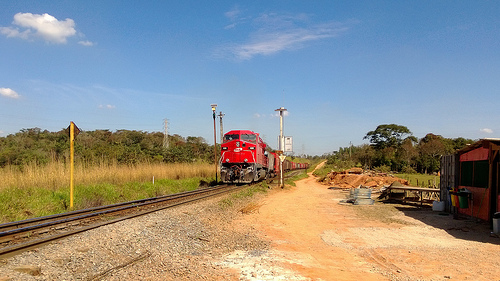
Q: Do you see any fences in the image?
A: No, there are no fences.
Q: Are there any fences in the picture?
A: No, there are no fences.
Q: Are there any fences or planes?
A: No, there are no fences or planes.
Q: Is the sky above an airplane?
A: No, the sky is above a train.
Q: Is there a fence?
A: No, there are no fences.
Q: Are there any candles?
A: No, there are no candles.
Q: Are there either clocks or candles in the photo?
A: No, there are no candles or clocks.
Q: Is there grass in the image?
A: Yes, there is grass.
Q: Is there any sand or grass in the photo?
A: Yes, there is grass.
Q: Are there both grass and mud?
A: No, there is grass but no mud.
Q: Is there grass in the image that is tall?
A: Yes, there is tall grass.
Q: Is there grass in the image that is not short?
A: Yes, there is tall grass.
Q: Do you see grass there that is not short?
A: Yes, there is tall grass.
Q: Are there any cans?
A: No, there are no cans.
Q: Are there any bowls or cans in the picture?
A: No, there are no cans or bowls.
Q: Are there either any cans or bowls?
A: No, there are no cans or bowls.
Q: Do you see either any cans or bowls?
A: No, there are no cans or bowls.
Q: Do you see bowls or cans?
A: No, there are no cans or bowls.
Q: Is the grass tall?
A: Yes, the grass is tall.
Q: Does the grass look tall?
A: Yes, the grass is tall.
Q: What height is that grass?
A: The grass is tall.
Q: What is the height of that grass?
A: The grass is tall.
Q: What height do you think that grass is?
A: The grass is tall.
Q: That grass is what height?
A: The grass is tall.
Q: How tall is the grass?
A: The grass is tall.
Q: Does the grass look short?
A: No, the grass is tall.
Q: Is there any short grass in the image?
A: No, there is grass but it is tall.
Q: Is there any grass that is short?
A: No, there is grass but it is tall.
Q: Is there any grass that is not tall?
A: No, there is grass but it is tall.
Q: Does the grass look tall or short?
A: The grass is tall.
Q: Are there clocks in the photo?
A: No, there are no clocks.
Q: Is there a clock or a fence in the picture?
A: No, there are no clocks or fences.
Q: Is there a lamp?
A: No, there are no lamps.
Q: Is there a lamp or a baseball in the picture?
A: No, there are no lamps or baseballs.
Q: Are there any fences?
A: No, there are no fences.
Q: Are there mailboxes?
A: No, there are no mailboxes.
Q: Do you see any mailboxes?
A: No, there are no mailboxes.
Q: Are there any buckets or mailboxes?
A: No, there are no mailboxes or buckets.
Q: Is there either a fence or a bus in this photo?
A: No, there are no fences or buses.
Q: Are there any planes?
A: No, there are no planes.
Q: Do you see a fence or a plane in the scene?
A: No, there are no airplanes or fences.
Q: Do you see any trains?
A: Yes, there is a train.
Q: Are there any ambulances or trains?
A: Yes, there is a train.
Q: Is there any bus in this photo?
A: No, there are no buses.